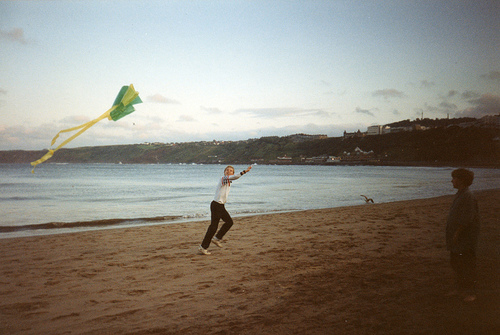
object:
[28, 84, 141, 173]
kite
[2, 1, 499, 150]
sky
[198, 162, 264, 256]
man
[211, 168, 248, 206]
shirt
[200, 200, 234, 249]
pants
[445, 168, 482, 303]
boy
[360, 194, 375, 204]
bird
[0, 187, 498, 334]
sand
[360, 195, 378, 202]
wings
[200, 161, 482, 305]
people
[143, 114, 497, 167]
houses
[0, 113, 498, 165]
hill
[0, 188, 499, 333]
beach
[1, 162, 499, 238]
water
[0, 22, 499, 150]
clouds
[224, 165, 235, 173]
blonde hair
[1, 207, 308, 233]
wave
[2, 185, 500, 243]
shore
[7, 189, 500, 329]
footprints